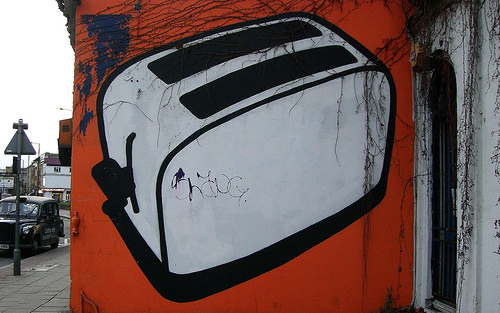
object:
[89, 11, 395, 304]
art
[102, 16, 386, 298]
painting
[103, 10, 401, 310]
wall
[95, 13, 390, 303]
toaster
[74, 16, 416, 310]
background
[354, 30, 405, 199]
vines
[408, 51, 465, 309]
window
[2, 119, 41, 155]
sign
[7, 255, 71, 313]
sidewalk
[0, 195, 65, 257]
car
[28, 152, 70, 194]
buildngs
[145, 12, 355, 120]
slots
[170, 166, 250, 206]
writing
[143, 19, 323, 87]
openings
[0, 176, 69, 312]
road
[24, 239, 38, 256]
tire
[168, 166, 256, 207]
signature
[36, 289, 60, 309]
cracks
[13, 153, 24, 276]
signpost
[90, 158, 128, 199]
handle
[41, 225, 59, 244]
letting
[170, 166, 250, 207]
kwg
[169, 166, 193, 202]
letters